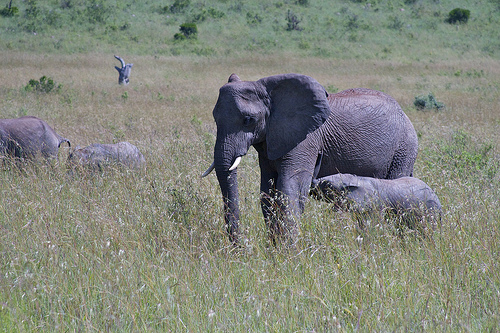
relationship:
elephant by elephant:
[203, 73, 421, 250] [316, 148, 444, 231]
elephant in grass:
[203, 73, 421, 250] [167, 271, 169, 332]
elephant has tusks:
[203, 73, 421, 250] [230, 154, 243, 173]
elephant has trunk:
[203, 73, 421, 250] [211, 154, 241, 244]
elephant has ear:
[203, 73, 421, 250] [270, 76, 331, 157]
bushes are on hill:
[173, 23, 199, 46] [141, 1, 304, 63]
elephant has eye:
[203, 73, 421, 250] [244, 112, 252, 127]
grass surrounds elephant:
[167, 271, 169, 332] [203, 73, 421, 250]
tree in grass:
[115, 55, 133, 86] [167, 271, 169, 332]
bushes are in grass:
[173, 23, 199, 46] [167, 271, 169, 332]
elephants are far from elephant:
[0, 114, 147, 166] [203, 73, 421, 250]